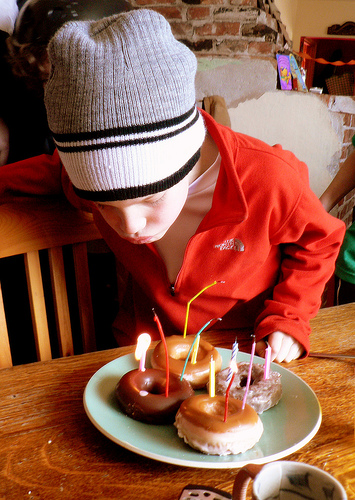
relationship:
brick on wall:
[189, 12, 243, 40] [130, 0, 354, 228]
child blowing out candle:
[31, 13, 335, 349] [218, 370, 235, 420]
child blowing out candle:
[31, 13, 335, 349] [180, 287, 198, 342]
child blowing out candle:
[31, 13, 335, 349] [161, 345, 173, 396]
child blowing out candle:
[31, 13, 335, 349] [260, 343, 273, 377]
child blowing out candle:
[31, 13, 335, 349] [227, 336, 243, 370]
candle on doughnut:
[218, 370, 235, 420] [186, 388, 269, 457]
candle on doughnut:
[161, 345, 173, 396] [121, 369, 190, 413]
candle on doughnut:
[227, 336, 243, 370] [216, 357, 285, 411]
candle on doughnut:
[260, 343, 273, 377] [216, 357, 285, 411]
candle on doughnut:
[180, 287, 198, 342] [159, 333, 214, 374]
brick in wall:
[189, 12, 243, 40] [166, 12, 345, 139]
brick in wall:
[189, 12, 243, 40] [155, 1, 288, 61]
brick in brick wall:
[189, 12, 243, 40] [127, 2, 291, 82]